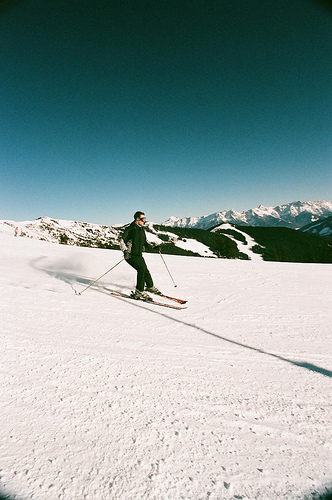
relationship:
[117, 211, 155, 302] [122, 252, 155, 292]
man has pants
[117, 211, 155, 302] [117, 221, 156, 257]
man wearing a black jacket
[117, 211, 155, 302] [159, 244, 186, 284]
man has poles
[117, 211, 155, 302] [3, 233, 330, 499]
man on down hill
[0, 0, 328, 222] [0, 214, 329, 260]
sky above mountain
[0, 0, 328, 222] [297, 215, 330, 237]
sky above mountain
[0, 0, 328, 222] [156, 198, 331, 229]
sky above mountain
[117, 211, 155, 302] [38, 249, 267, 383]
man skiing down slope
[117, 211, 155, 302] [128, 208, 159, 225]
man wearing goggles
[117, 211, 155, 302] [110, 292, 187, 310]
man using ski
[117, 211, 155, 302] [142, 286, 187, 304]
man using ski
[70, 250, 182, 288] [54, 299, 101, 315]
ski pole digging into snow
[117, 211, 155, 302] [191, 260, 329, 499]
man skiing downhill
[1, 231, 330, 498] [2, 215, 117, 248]
snow covered mountains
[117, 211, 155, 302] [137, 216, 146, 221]
man wearing goggles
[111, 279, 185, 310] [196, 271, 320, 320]
skis in snow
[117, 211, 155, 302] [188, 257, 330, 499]
man skiing on hill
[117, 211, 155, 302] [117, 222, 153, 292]
man wearing clothes